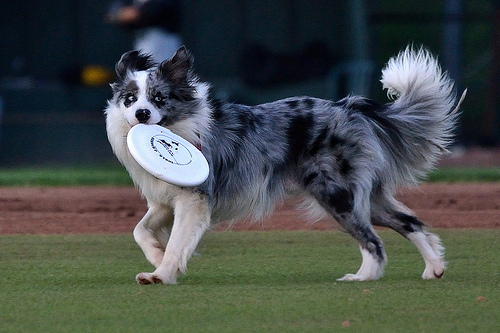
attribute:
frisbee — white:
[125, 127, 221, 189]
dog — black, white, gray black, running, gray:
[88, 45, 491, 288]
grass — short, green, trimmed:
[425, 303, 474, 325]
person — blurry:
[112, 11, 209, 47]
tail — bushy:
[366, 60, 462, 193]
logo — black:
[149, 136, 196, 171]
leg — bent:
[135, 205, 168, 270]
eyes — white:
[109, 90, 176, 102]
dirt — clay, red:
[52, 194, 93, 225]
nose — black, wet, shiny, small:
[132, 107, 150, 124]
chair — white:
[320, 47, 383, 103]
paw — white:
[413, 226, 439, 272]